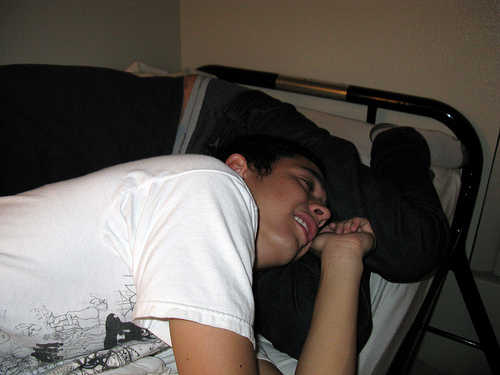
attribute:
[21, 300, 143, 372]
drawing — white, black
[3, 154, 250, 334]
shirt — white, short sleeved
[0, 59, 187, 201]
sweatshirt — black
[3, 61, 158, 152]
blackshirt — black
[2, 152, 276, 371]
shirt — white, short sleeved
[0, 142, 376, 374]
person — laying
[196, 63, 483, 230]
bar — black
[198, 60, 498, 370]
metal frame — black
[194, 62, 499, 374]
bar — metal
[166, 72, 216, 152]
border — white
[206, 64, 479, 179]
headboard — curved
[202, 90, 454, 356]
pants — black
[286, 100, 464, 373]
sheet — white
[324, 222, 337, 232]
finger — bent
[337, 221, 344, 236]
finger — bent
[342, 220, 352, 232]
finger — bent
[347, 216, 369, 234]
finger — bent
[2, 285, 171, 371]
design — black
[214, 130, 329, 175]
hair — black, short